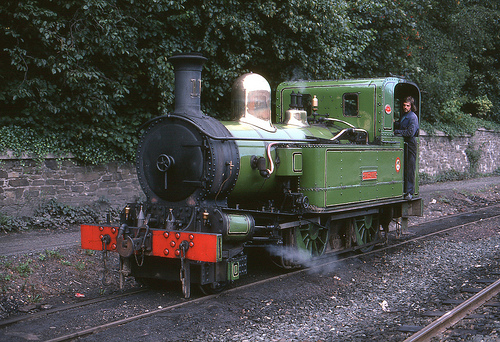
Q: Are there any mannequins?
A: No, there are no mannequins.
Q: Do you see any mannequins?
A: No, there are no mannequins.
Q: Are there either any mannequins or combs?
A: No, there are no mannequins or combs.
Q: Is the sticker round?
A: Yes, the sticker is round.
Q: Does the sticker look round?
A: Yes, the sticker is round.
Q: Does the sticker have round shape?
A: Yes, the sticker is round.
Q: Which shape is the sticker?
A: The sticker is round.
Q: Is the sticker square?
A: No, the sticker is round.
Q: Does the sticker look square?
A: No, the sticker is round.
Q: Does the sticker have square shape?
A: No, the sticker is round.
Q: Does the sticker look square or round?
A: The sticker is round.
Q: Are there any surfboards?
A: No, there are no surfboards.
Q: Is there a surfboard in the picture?
A: No, there are no surfboards.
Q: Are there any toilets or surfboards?
A: No, there are no surfboards or toilets.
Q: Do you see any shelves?
A: No, there are no shelves.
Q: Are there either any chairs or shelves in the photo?
A: No, there are no shelves or chairs.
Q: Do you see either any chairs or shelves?
A: No, there are no shelves or chairs.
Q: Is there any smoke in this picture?
A: Yes, there is smoke.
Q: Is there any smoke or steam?
A: Yes, there is smoke.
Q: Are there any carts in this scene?
A: No, there are no carts.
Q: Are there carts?
A: No, there are no carts.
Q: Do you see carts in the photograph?
A: No, there are no carts.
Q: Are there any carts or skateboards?
A: No, there are no carts or skateboards.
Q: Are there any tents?
A: No, there are no tents.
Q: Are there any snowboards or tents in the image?
A: No, there are no tents or snowboards.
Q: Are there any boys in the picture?
A: No, there are no boys.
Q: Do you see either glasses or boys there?
A: No, there are no boys or glasses.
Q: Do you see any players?
A: No, there are no players.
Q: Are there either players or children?
A: No, there are no players or children.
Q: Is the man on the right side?
A: Yes, the man is on the right of the image.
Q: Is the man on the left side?
A: No, the man is on the right of the image.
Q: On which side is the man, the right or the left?
A: The man is on the right of the image.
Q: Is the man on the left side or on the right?
A: The man is on the right of the image.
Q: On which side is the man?
A: The man is on the right of the image.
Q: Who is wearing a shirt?
A: The man is wearing a shirt.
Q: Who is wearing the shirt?
A: The man is wearing a shirt.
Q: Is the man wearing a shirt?
A: Yes, the man is wearing a shirt.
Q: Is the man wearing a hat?
A: No, the man is wearing a shirt.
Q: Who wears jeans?
A: The man wears jeans.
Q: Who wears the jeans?
A: The man wears jeans.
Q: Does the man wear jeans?
A: Yes, the man wears jeans.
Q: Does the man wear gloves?
A: No, the man wears jeans.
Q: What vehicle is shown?
A: The vehicle is a locomotive.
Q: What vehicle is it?
A: The vehicle is a locomotive.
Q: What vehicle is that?
A: This is a locomotive.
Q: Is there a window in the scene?
A: Yes, there is a window.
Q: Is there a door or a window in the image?
A: Yes, there is a window.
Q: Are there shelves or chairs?
A: No, there are no shelves or chairs.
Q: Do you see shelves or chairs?
A: No, there are no shelves or chairs.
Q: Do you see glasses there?
A: No, there are no glasses.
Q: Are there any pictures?
A: No, there are no pictures.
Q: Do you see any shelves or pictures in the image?
A: No, there are no pictures or shelves.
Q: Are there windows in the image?
A: Yes, there is a window.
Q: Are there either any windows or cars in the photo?
A: Yes, there is a window.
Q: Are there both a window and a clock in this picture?
A: No, there is a window but no clocks.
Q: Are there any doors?
A: No, there are no doors.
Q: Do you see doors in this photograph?
A: No, there are no doors.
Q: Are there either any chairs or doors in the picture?
A: No, there are no doors or chairs.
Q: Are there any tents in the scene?
A: No, there are no tents.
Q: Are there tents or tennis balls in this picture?
A: No, there are no tents or tennis balls.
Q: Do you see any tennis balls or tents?
A: No, there are no tents or tennis balls.